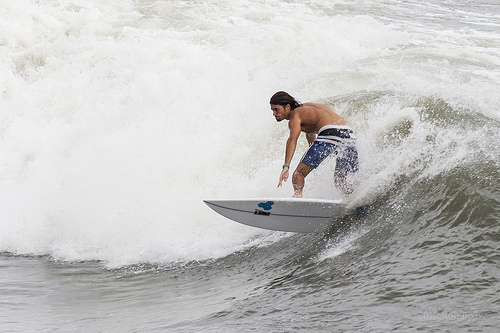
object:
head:
[267, 90, 295, 122]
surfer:
[271, 90, 360, 199]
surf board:
[202, 198, 357, 235]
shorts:
[301, 123, 362, 173]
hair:
[268, 89, 303, 106]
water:
[0, 0, 496, 329]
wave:
[266, 90, 500, 269]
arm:
[270, 117, 303, 189]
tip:
[193, 196, 319, 218]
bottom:
[200, 200, 341, 229]